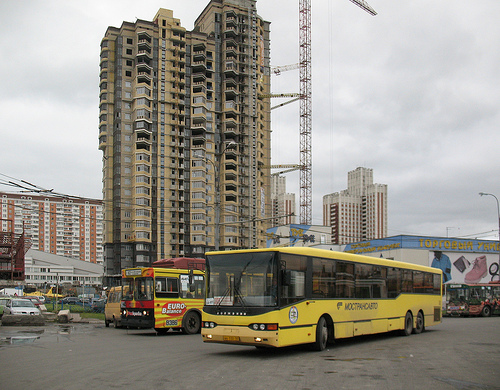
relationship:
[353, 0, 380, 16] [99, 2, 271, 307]
crane next to building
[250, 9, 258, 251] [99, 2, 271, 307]
ladder to go up building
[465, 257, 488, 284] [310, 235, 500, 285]
shoe on side of building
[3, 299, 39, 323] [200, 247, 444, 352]
car in front of bus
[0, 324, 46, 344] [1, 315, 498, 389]
water in road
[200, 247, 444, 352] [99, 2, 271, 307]
bus under building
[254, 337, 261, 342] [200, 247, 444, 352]
light on front of bus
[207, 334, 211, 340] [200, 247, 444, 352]
light on front of bus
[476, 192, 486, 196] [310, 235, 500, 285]
light over building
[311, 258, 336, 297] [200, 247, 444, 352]
window on bus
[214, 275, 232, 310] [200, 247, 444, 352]
wiper on bus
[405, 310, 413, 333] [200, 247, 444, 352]
wheel of bus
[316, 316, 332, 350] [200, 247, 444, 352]
wheel of bus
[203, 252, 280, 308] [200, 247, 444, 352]
windshield of bus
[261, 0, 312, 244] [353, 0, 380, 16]
structure for crane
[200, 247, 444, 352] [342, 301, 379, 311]
bus has writing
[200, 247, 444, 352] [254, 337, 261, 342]
bus has light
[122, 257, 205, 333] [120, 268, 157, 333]
bus has red front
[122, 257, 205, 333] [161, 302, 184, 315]
bus has writing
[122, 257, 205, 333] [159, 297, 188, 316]
bus has decal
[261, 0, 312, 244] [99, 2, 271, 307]
structure attached to building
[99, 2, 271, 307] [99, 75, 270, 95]
building has story